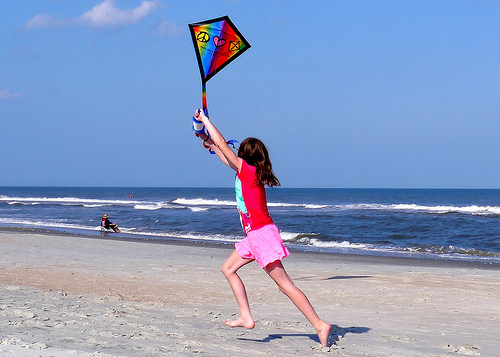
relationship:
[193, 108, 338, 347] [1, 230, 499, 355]
girl on beach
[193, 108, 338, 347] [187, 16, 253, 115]
girl flying kite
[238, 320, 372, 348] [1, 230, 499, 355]
shadow on beach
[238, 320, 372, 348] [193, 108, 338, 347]
shadow of girl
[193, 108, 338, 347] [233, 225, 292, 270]
girl wearing shorts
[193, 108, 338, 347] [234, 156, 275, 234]
girl wearing shirt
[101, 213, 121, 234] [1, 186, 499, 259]
person near water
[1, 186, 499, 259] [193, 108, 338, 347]
water behind girl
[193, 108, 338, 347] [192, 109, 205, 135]
girl holding handle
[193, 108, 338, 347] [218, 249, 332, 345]
girl has legs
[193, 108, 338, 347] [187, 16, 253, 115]
girl holding kite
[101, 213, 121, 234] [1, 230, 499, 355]
person on beach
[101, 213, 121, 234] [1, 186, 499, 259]
person sitting near water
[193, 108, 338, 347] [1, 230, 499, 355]
girl running on beach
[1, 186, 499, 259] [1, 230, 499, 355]
water next to beach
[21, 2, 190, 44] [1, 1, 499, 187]
clouds in sky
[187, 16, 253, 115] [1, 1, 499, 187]
kite in sky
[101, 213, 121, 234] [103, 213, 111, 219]
person wearing hat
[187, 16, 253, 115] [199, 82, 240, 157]
kite has tail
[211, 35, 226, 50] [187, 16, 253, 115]
heart on kite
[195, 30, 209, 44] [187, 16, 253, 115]
peace sign on kite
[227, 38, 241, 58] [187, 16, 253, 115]
kite design on kite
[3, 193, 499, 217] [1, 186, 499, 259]
wave in water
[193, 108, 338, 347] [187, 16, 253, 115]
girl playing with kite